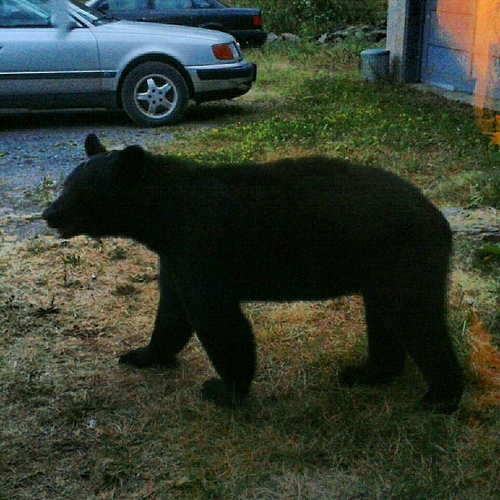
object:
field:
[3, 6, 499, 492]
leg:
[184, 302, 254, 385]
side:
[164, 157, 448, 300]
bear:
[40, 133, 462, 414]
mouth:
[48, 224, 77, 237]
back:
[194, 155, 393, 180]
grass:
[185, 71, 500, 500]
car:
[0, 0, 259, 127]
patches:
[0, 231, 499, 498]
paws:
[202, 377, 245, 402]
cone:
[361, 49, 390, 82]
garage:
[386, 0, 500, 112]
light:
[254, 16, 262, 25]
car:
[86, 1, 267, 49]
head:
[43, 134, 142, 239]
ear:
[85, 133, 105, 155]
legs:
[370, 291, 463, 391]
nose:
[42, 208, 58, 220]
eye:
[78, 186, 94, 197]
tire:
[121, 62, 188, 127]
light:
[212, 41, 241, 60]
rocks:
[267, 32, 298, 43]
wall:
[386, 0, 404, 82]